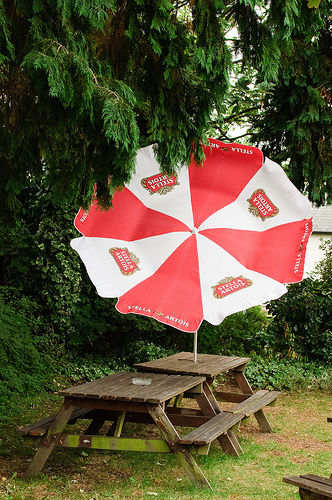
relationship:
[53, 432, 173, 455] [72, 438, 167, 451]
wood has mold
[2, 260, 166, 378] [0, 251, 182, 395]
hillside has plants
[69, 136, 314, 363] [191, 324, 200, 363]
umbrella has pole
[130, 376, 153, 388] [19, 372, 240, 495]
ashtray on top of table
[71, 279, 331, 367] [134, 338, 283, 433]
bushes are behind table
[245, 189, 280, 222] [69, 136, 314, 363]
beer manufacturer printed on umbrella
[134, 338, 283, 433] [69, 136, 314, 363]
table has an umbrella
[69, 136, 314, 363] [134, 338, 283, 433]
umbrella on top of table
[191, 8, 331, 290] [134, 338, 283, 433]
buiding behind table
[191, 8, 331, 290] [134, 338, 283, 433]
building behind table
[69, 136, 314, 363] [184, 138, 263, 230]
umbrella has red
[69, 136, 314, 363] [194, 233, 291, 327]
umbrella has white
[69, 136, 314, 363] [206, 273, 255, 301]
umbrella has logo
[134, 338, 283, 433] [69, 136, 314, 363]
table holding umbrella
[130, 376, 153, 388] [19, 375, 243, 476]
ashtray on top of table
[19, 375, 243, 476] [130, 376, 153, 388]
table has an ashtray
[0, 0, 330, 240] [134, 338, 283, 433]
trees are behind table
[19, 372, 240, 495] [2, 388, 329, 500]
table are on top of grass